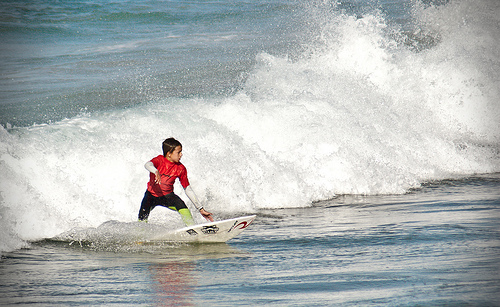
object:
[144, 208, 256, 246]
surfboard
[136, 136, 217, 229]
boy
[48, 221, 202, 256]
water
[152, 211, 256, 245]
surfboard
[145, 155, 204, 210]
shirt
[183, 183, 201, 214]
sleeve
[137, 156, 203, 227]
wet suit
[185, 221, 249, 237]
design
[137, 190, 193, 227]
pants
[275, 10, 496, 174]
ocean wave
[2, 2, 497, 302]
ocean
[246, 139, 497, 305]
water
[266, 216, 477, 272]
ripples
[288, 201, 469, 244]
ripples